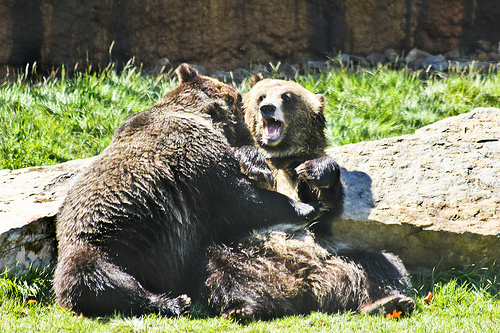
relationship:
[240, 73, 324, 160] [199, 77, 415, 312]
head of bear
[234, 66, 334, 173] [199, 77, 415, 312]
head of bear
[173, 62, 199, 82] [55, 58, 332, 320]
ear of bear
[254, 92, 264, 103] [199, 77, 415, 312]
eye of bear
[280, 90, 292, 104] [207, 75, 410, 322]
eye of bear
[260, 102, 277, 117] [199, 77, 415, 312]
nose of bear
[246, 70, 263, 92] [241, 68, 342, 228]
ear of bear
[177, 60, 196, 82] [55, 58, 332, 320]
ear of bear